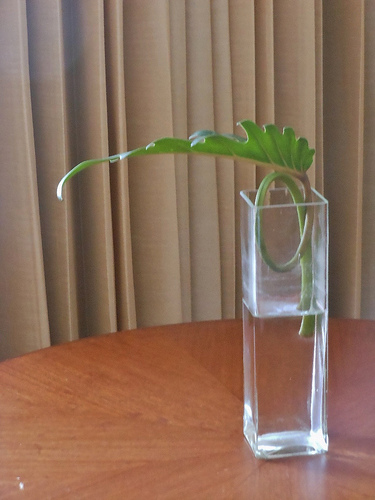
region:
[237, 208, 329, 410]
this is a glass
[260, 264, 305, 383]
the glass is shinny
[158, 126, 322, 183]
this is a leaf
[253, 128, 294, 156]
the leaf is green in color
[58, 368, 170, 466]
this is a table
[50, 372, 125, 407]
the table is brown in color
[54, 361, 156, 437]
the table is wooden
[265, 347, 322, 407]
there is a liquid in the glass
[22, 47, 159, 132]
this is a wall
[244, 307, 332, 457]
the glass is half filled with the liquid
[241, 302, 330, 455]
Half of a glass vase with water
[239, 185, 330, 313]
Top half of a glass vase with a plant in it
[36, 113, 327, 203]
Green leaf of a plant in a vase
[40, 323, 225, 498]
Wooden table top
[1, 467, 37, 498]
Reflection off of the shine of a table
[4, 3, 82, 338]
Blinds on a window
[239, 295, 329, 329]
Water fill line on a glass vase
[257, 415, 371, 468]
Shadow of a glass vase on a table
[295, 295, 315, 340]
Stem of a plant offset in the water of a vase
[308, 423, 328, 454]
Reflection of light off a glass vase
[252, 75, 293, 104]
part of a curtain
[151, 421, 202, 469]
part of a table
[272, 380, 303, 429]
part of a glass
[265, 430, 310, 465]
bottom of a glass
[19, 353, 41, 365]
edge of a table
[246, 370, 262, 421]
edge of a glass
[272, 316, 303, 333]
part of a level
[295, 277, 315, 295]
part of a stem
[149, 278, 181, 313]
part of a curtain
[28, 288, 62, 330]
edge of a curtain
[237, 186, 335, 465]
vase half filled with water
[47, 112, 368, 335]
green plant sticking out of the top of a vase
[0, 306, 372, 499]
vase sitting on a round wooden table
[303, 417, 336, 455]
light reflecting off of vase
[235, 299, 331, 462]
clear water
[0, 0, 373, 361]
tan curtains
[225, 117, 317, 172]
jagged edges of plant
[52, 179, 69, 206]
light reflecting off the tip of the plant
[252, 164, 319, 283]
stalk of plant curled into a circle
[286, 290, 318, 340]
bottom of the plant just barely sticking in the water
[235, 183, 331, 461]
a square glass vase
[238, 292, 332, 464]
water in the vase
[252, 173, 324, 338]
the stem of a plant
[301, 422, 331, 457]
light on the vase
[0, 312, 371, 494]
a round wooden table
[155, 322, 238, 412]
a line on the table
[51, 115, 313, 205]
a leaf on the plant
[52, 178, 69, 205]
light on the leaf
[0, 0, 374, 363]
a white curtain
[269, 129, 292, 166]
a vein on the leaf